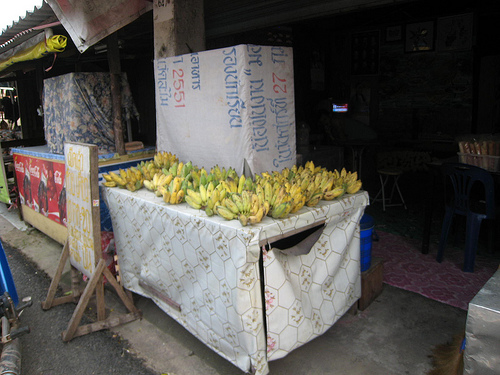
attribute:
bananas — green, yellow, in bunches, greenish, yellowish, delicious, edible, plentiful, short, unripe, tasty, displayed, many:
[100, 151, 364, 226]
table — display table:
[103, 161, 371, 374]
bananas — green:
[183, 168, 221, 192]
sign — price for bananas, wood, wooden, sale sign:
[43, 141, 144, 342]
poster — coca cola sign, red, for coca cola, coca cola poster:
[12, 153, 67, 228]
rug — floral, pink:
[372, 196, 500, 312]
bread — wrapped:
[459, 136, 498, 169]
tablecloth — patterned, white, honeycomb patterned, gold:
[101, 184, 374, 374]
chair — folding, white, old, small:
[372, 166, 408, 211]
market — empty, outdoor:
[2, 0, 499, 372]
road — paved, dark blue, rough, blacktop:
[0, 239, 152, 374]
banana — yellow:
[152, 172, 159, 189]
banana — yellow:
[184, 194, 202, 210]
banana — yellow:
[249, 204, 264, 224]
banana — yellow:
[105, 170, 127, 187]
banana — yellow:
[176, 160, 184, 178]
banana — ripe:
[323, 184, 343, 200]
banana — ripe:
[199, 182, 206, 198]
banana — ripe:
[168, 187, 178, 204]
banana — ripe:
[101, 181, 118, 187]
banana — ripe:
[289, 193, 307, 213]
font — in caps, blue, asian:
[223, 46, 292, 167]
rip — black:
[263, 220, 328, 256]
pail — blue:
[359, 213, 379, 268]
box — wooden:
[358, 256, 388, 307]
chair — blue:
[434, 161, 500, 271]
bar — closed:
[204, 1, 499, 310]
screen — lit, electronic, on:
[331, 100, 349, 113]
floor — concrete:
[1, 201, 467, 374]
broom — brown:
[428, 330, 464, 374]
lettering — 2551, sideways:
[172, 67, 187, 110]